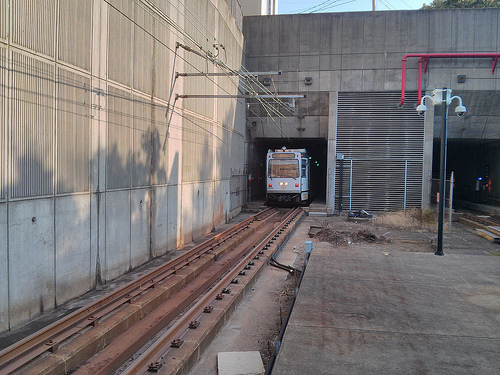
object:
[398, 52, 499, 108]
pipe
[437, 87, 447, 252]
pole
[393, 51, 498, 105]
pipes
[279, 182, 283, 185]
yellow light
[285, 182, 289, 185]
yellow light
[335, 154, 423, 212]
pipes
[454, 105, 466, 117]
cameras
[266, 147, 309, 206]
front end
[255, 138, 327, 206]
tunnel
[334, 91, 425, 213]
door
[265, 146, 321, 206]
train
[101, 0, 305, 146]
cables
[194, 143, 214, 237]
shadow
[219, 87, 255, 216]
shadow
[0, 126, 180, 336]
shadow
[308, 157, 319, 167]
lights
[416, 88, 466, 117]
lights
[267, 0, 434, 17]
sky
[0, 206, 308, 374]
rail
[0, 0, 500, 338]
wall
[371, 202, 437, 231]
grass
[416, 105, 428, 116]
cameras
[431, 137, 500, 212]
tunnel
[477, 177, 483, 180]
lights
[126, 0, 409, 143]
electric lines